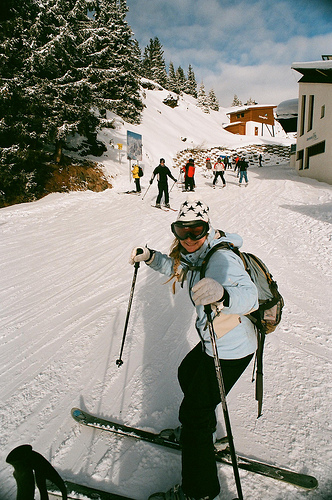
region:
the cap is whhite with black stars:
[170, 200, 213, 220]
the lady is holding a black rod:
[113, 238, 155, 373]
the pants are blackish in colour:
[179, 346, 224, 443]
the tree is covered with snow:
[35, 26, 118, 90]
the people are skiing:
[137, 163, 254, 179]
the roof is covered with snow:
[227, 106, 279, 115]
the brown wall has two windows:
[234, 112, 247, 117]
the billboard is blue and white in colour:
[127, 131, 146, 161]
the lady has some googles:
[171, 223, 212, 238]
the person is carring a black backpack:
[133, 165, 143, 190]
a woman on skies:
[7, 201, 320, 495]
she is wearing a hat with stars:
[169, 196, 214, 221]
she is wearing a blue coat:
[151, 228, 260, 360]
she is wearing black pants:
[160, 333, 257, 498]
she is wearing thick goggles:
[169, 220, 207, 240]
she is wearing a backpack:
[232, 241, 289, 407]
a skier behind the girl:
[141, 157, 180, 213]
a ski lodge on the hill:
[221, 103, 278, 139]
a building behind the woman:
[290, 49, 330, 184]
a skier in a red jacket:
[177, 159, 197, 189]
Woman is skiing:
[33, 200, 317, 498]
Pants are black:
[176, 338, 251, 495]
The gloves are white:
[129, 245, 220, 302]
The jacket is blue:
[145, 228, 255, 357]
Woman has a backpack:
[239, 251, 279, 334]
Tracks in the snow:
[2, 224, 102, 352]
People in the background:
[129, 152, 260, 209]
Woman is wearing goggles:
[169, 218, 205, 238]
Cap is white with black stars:
[176, 193, 207, 218]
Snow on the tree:
[1, 41, 139, 154]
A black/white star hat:
[175, 196, 216, 226]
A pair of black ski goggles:
[166, 220, 209, 242]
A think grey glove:
[188, 273, 227, 315]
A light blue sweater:
[138, 224, 262, 361]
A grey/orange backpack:
[238, 240, 292, 336]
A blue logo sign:
[70, 406, 82, 420]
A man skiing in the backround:
[140, 155, 181, 215]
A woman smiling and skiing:
[79, 195, 299, 497]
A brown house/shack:
[221, 102, 280, 143]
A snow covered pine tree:
[193, 78, 211, 117]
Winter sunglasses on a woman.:
[169, 221, 210, 239]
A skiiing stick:
[114, 248, 142, 367]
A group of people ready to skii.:
[126, 157, 254, 209]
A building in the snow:
[223, 104, 277, 138]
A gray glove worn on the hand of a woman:
[191, 279, 224, 303]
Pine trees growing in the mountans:
[0, 14, 136, 197]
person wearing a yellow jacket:
[131, 163, 140, 190]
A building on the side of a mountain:
[295, 60, 330, 181]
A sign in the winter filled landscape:
[125, 130, 143, 161]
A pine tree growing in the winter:
[139, 34, 166, 84]